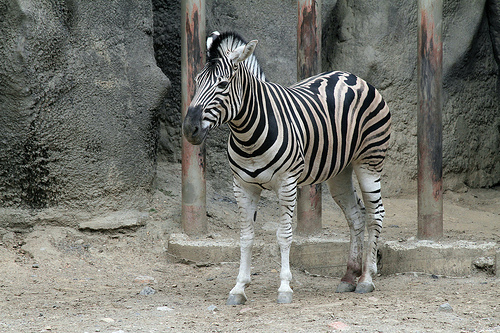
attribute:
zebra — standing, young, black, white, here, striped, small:
[181, 28, 407, 294]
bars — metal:
[158, 0, 498, 265]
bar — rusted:
[175, 1, 217, 239]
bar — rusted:
[290, 1, 326, 230]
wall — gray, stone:
[7, 4, 497, 274]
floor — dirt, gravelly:
[6, 182, 499, 325]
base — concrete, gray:
[161, 224, 500, 274]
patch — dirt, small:
[307, 187, 500, 232]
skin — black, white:
[204, 72, 394, 260]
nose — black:
[182, 111, 205, 144]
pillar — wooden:
[179, 0, 210, 231]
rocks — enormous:
[5, 0, 493, 223]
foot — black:
[227, 293, 247, 308]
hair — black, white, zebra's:
[207, 28, 266, 88]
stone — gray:
[160, 238, 500, 264]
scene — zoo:
[7, 3, 498, 314]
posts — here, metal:
[172, 7, 448, 237]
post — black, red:
[414, 0, 448, 237]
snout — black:
[181, 106, 207, 147]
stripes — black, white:
[202, 75, 382, 191]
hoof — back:
[277, 287, 296, 311]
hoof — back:
[335, 279, 355, 294]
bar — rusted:
[415, 1, 449, 238]